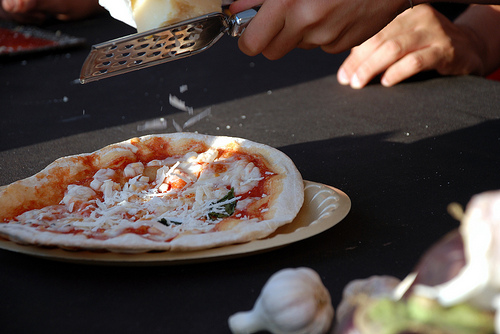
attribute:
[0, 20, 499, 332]
table — in the picture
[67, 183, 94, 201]
garlic — small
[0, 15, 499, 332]
tablecloth — black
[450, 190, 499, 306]
garlic — small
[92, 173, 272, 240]
cheese — grated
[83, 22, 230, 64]
garlic — small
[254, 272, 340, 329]
garlic — small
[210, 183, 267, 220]
leaf — in the picture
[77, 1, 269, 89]
grater — metal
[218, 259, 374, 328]
garlic — white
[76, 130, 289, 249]
pizza — raw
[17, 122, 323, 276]
pizza — unbaked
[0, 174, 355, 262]
plate — styrofoam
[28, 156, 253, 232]
cheese — white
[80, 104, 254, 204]
cheese — in the picture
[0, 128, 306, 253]
pizza — in the picture, uncooked, personal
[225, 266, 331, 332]
garlic — small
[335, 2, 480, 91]
hand — resting